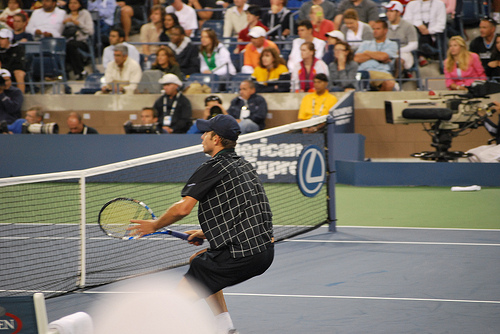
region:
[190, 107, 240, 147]
THE MAN IS WEARING A BLACK HAT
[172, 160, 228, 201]
THE MAN HAS BLACK SLEEVES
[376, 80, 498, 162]
THIS IS A LARGE CAMERA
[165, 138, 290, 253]
THE MAN IS WEARING A BLACK AND WHITE SHIRT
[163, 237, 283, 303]
THE MAN IS WEARING BLACK SHORTS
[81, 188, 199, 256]
THE MAN IS HOLDING A RACKET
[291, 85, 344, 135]
THE MAN IS WEARING A YELLOW SHIRT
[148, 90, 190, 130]
THE MAN IS WEARING A LANYARD WITH A PASS ON IT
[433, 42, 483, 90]
THE WOMAN IS WEARING A PINK SHIRT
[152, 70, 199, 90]
THE MAN IS WEARING A WHITE HAT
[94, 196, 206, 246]
tennis racket in a man's hand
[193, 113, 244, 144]
dark hat on a tennis player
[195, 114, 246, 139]
cap on a tennis player's head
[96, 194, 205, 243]
white blue and black tennis racket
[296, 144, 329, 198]
white and blue circular design on a tennis net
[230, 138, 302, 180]
white bold print on a wall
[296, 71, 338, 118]
man wearing a yellow shirt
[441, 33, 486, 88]
woman wearing a pink blazer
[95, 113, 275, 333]
man playing tennis on a court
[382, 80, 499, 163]
tan and black camera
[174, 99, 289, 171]
the head of a man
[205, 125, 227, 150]
the ear of a man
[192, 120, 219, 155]
the face of a man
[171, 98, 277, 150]
a man wearing a hat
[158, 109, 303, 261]
a man wearing a shirt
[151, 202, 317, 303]
a man wearing shorts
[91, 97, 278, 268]
a man holding a tennis racket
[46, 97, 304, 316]
a man playing tennis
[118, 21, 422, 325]
a man on a tennis court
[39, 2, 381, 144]
people watching a tennis match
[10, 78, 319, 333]
person playing in tennis match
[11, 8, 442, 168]
spectators watching tennis match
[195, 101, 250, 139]
man wearing blue hat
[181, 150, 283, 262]
man wearing plaid shirt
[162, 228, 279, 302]
man wearing black shorts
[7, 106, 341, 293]
tennis net has white trim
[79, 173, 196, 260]
man holding blue and white tennis rack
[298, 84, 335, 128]
person wearing yellow shirt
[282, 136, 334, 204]
blue emblem on tennis net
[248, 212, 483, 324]
tennis court is blue